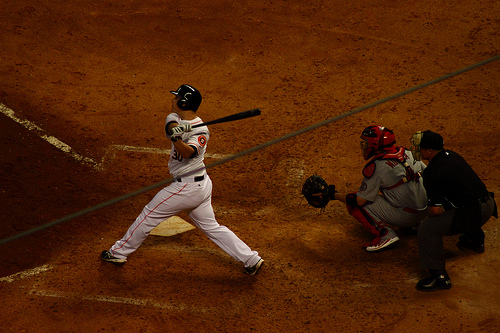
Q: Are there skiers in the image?
A: No, there are no skiers.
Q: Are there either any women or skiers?
A: No, there are no skiers or women.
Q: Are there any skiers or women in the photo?
A: No, there are no skiers or women.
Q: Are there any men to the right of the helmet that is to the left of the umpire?
A: No, the man is to the left of the helmet.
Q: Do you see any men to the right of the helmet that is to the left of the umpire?
A: No, the man is to the left of the helmet.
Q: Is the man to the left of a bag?
A: No, the man is to the left of the helmet.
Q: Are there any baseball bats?
A: Yes, there is a baseball bat.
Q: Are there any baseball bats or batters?
A: Yes, there is a baseball bat.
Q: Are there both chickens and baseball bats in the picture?
A: No, there is a baseball bat but no chickens.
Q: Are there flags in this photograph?
A: No, there are no flags.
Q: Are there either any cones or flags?
A: No, there are no flags or cones.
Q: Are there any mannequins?
A: No, there are no mannequins.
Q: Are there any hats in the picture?
A: Yes, there is a hat.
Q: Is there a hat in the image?
A: Yes, there is a hat.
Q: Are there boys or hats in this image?
A: Yes, there is a hat.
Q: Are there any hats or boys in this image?
A: Yes, there is a hat.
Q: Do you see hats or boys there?
A: Yes, there is a hat.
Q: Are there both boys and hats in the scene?
A: No, there is a hat but no boys.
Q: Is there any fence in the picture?
A: No, there are no fences.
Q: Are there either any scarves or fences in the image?
A: No, there are no fences or scarves.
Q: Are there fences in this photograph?
A: No, there are no fences.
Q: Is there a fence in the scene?
A: No, there are no fences.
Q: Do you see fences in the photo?
A: No, there are no fences.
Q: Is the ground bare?
A: Yes, the ground is bare.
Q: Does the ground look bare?
A: Yes, the ground is bare.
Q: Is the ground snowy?
A: No, the ground is bare.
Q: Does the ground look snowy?
A: No, the ground is bare.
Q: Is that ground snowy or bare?
A: The ground is bare.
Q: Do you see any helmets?
A: Yes, there is a helmet.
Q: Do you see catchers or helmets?
A: Yes, there is a helmet.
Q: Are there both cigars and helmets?
A: No, there is a helmet but no cigars.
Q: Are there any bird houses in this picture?
A: No, there are no bird houses.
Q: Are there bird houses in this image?
A: No, there are no bird houses.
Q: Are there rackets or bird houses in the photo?
A: No, there are no bird houses or rackets.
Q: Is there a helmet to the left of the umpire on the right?
A: Yes, there is a helmet to the left of the umpire.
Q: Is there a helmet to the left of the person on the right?
A: Yes, there is a helmet to the left of the umpire.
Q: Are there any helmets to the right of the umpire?
A: No, the helmet is to the left of the umpire.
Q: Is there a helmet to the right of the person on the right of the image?
A: No, the helmet is to the left of the umpire.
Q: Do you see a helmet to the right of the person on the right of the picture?
A: No, the helmet is to the left of the umpire.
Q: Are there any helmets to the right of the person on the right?
A: No, the helmet is to the left of the umpire.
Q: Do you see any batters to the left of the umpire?
A: No, there is a helmet to the left of the umpire.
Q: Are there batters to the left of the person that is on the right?
A: No, there is a helmet to the left of the umpire.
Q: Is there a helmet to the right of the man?
A: Yes, there is a helmet to the right of the man.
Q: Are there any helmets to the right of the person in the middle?
A: Yes, there is a helmet to the right of the man.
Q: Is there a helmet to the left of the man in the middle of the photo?
A: No, the helmet is to the right of the man.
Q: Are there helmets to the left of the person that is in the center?
A: No, the helmet is to the right of the man.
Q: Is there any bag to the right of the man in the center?
A: No, there is a helmet to the right of the man.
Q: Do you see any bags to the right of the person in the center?
A: No, there is a helmet to the right of the man.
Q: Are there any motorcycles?
A: No, there are no motorcycles.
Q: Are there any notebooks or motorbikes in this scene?
A: No, there are no motorbikes or notebooks.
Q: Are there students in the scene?
A: No, there are no students.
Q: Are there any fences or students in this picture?
A: No, there are no students or fences.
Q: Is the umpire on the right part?
A: Yes, the umpire is on the right of the image.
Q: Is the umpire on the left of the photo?
A: No, the umpire is on the right of the image.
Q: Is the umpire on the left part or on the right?
A: The umpire is on the right of the image.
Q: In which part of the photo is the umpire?
A: The umpire is on the right of the image.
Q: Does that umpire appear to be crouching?
A: Yes, the umpire is crouching.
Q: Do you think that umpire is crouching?
A: Yes, the umpire is crouching.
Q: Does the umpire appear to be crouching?
A: Yes, the umpire is crouching.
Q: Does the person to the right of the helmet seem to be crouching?
A: Yes, the umpire is crouching.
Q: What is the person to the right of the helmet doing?
A: The umpire is crouching.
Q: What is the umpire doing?
A: The umpire is crouching.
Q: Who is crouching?
A: The umpire is crouching.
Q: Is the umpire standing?
A: No, the umpire is crouching.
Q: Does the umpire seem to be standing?
A: No, the umpire is crouching.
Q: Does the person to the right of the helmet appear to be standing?
A: No, the umpire is crouching.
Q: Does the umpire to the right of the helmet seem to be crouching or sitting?
A: The umpire is crouching.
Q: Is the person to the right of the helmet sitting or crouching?
A: The umpire is crouching.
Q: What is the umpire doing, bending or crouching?
A: The umpire is crouching.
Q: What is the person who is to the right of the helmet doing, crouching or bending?
A: The umpire is crouching.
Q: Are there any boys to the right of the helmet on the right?
A: No, there is an umpire to the right of the helmet.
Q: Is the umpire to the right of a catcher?
A: No, the umpire is to the right of the helmet.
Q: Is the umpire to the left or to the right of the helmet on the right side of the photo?
A: The umpire is to the right of the helmet.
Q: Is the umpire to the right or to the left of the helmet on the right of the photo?
A: The umpire is to the right of the helmet.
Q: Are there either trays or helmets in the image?
A: Yes, there is a helmet.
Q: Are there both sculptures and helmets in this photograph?
A: No, there is a helmet but no sculptures.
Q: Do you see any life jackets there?
A: No, there are no life jackets.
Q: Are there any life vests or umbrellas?
A: No, there are no life vests or umbrellas.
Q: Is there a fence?
A: No, there are no fences.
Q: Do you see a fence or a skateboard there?
A: No, there are no fences or skateboards.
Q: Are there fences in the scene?
A: No, there are no fences.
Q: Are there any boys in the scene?
A: No, there are no boys.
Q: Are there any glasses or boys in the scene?
A: No, there are no boys or glasses.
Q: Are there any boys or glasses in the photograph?
A: No, there are no boys or glasses.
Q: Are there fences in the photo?
A: No, there are no fences.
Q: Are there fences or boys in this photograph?
A: No, there are no fences or boys.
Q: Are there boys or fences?
A: No, there are no fences or boys.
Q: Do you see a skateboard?
A: No, there are no skateboards.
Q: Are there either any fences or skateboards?
A: No, there are no skateboards or fences.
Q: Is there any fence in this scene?
A: No, there are no fences.